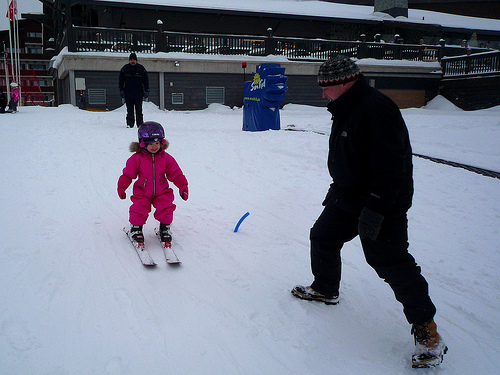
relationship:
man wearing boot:
[291, 57, 450, 369] [410, 317, 449, 368]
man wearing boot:
[291, 57, 450, 369] [290, 286, 341, 304]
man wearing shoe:
[291, 57, 450, 369] [293, 264, 350, 308]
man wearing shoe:
[291, 57, 450, 369] [404, 317, 450, 370]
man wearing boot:
[291, 57, 450, 369] [279, 259, 346, 314]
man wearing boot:
[291, 57, 450, 369] [401, 311, 455, 362]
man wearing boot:
[291, 57, 450, 369] [292, 270, 343, 308]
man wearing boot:
[291, 57, 450, 369] [404, 313, 452, 368]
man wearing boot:
[295, 51, 395, 146] [292, 270, 343, 308]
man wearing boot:
[295, 51, 395, 146] [404, 311, 447, 364]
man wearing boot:
[291, 57, 450, 369] [290, 273, 346, 313]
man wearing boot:
[291, 57, 450, 369] [398, 311, 452, 370]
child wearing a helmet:
[116, 120, 190, 242] [134, 120, 169, 142]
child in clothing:
[110, 114, 193, 242] [111, 150, 185, 204]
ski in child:
[119, 218, 157, 276] [103, 114, 193, 261]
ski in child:
[145, 219, 180, 267] [103, 114, 193, 261]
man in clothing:
[112, 49, 155, 133] [118, 65, 150, 111]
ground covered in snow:
[32, 172, 132, 242] [4, 125, 159, 346]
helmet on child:
[135, 121, 169, 148] [119, 114, 188, 180]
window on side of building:
[203, 87, 232, 109] [37, 0, 467, 123]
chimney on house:
[365, 0, 422, 23] [43, 1, 483, 111]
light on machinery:
[238, 57, 249, 71] [229, 50, 292, 139]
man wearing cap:
[112, 49, 155, 133] [121, 49, 138, 60]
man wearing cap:
[291, 57, 450, 369] [315, 52, 370, 84]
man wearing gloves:
[112, 41, 154, 133] [113, 86, 155, 108]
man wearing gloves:
[291, 57, 450, 369] [348, 198, 398, 247]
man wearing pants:
[112, 49, 155, 133] [122, 86, 144, 127]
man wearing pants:
[291, 57, 450, 369] [281, 185, 462, 353]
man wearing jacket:
[112, 49, 155, 133] [111, 59, 153, 103]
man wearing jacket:
[291, 57, 450, 369] [305, 70, 424, 218]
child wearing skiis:
[116, 120, 190, 242] [114, 212, 191, 272]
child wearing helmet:
[116, 120, 190, 242] [119, 214, 197, 276]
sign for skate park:
[232, 49, 292, 145] [1, 2, 482, 372]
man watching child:
[291, 57, 450, 369] [113, 113, 191, 248]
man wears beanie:
[291, 57, 450, 369] [306, 44, 368, 91]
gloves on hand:
[345, 204, 392, 251] [351, 201, 388, 248]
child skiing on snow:
[116, 120, 190, 242] [44, 226, 270, 362]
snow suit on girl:
[109, 146, 199, 231] [104, 116, 193, 245]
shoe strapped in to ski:
[153, 213, 174, 243] [155, 215, 173, 242]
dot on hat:
[319, 59, 334, 69] [307, 49, 373, 89]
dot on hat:
[327, 60, 334, 68] [314, 51, 354, 80]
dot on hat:
[324, 59, 332, 67] [314, 52, 354, 84]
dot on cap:
[335, 65, 346, 75] [315, 52, 365, 88]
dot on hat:
[330, 60, 340, 73] [320, 56, 355, 86]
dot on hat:
[332, 62, 345, 67] [320, 56, 355, 86]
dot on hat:
[339, 60, 346, 68] [320, 56, 355, 86]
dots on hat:
[321, 62, 345, 80] [317, 51, 357, 84]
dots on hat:
[325, 57, 345, 69] [322, 59, 355, 79]